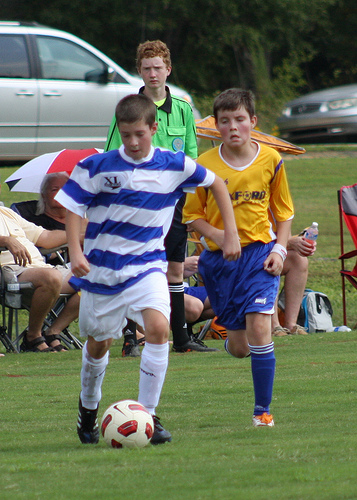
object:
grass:
[0, 144, 356, 499]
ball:
[99, 398, 155, 452]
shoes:
[75, 391, 101, 445]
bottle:
[300, 221, 319, 257]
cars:
[0, 18, 203, 161]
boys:
[181, 86, 295, 428]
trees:
[213, 1, 271, 96]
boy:
[64, 92, 243, 446]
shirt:
[52, 143, 216, 295]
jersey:
[181, 141, 296, 253]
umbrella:
[2, 148, 104, 195]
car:
[275, 84, 356, 146]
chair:
[336, 186, 356, 331]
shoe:
[251, 411, 274, 426]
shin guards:
[79, 340, 109, 411]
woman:
[34, 171, 145, 347]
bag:
[299, 290, 333, 335]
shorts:
[195, 238, 280, 332]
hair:
[114, 94, 156, 132]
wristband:
[269, 242, 288, 263]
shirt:
[103, 84, 198, 160]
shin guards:
[245, 342, 277, 415]